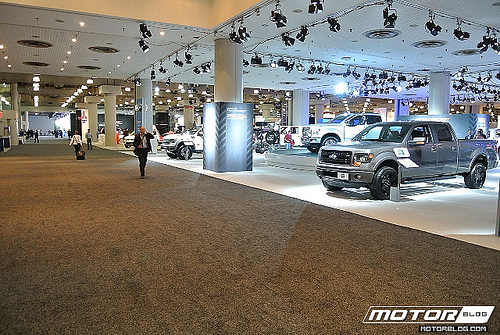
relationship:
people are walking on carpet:
[24, 125, 155, 175] [1, 141, 496, 332]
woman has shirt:
[68, 130, 88, 159] [68, 134, 87, 145]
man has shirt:
[131, 126, 149, 177] [140, 134, 148, 147]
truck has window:
[306, 114, 499, 203] [406, 123, 430, 143]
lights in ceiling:
[35, 14, 100, 74] [6, 13, 164, 123]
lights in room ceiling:
[39, 17, 133, 155] [79, 15, 197, 65]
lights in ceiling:
[38, 20, 145, 143] [23, 14, 147, 152]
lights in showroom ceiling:
[22, 0, 127, 147] [204, 1, 499, 106]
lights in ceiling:
[34, 2, 123, 122] [29, 18, 390, 140]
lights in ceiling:
[45, 17, 129, 144] [27, 20, 359, 104]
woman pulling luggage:
[56, 95, 124, 199] [56, 131, 90, 160]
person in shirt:
[279, 117, 302, 178] [276, 126, 303, 143]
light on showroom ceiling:
[273, 10, 289, 30] [4, 1, 497, 112]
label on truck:
[386, 144, 424, 176] [328, 119, 497, 211]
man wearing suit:
[124, 120, 154, 180] [129, 133, 159, 165]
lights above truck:
[226, 17, 411, 82] [306, 114, 499, 203]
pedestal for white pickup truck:
[252, 144, 383, 207] [350, 99, 480, 193]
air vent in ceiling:
[12, 37, 53, 51] [3, 4, 210, 83]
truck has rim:
[306, 114, 496, 203] [373, 164, 398, 193]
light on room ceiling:
[135, 19, 158, 59] [79, 15, 197, 65]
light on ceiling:
[232, 14, 253, 46] [208, 15, 282, 55]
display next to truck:
[391, 143, 419, 187] [314, 118, 484, 203]